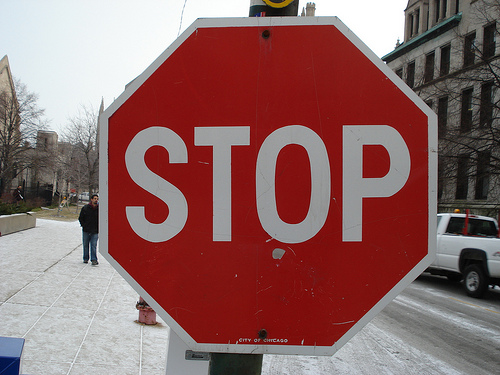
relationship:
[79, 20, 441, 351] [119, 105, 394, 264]
sign says stop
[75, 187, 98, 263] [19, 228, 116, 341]
man at sidewalk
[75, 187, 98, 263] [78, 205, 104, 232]
man wearing jacket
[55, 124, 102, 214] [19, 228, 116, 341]
tree at sidewalk